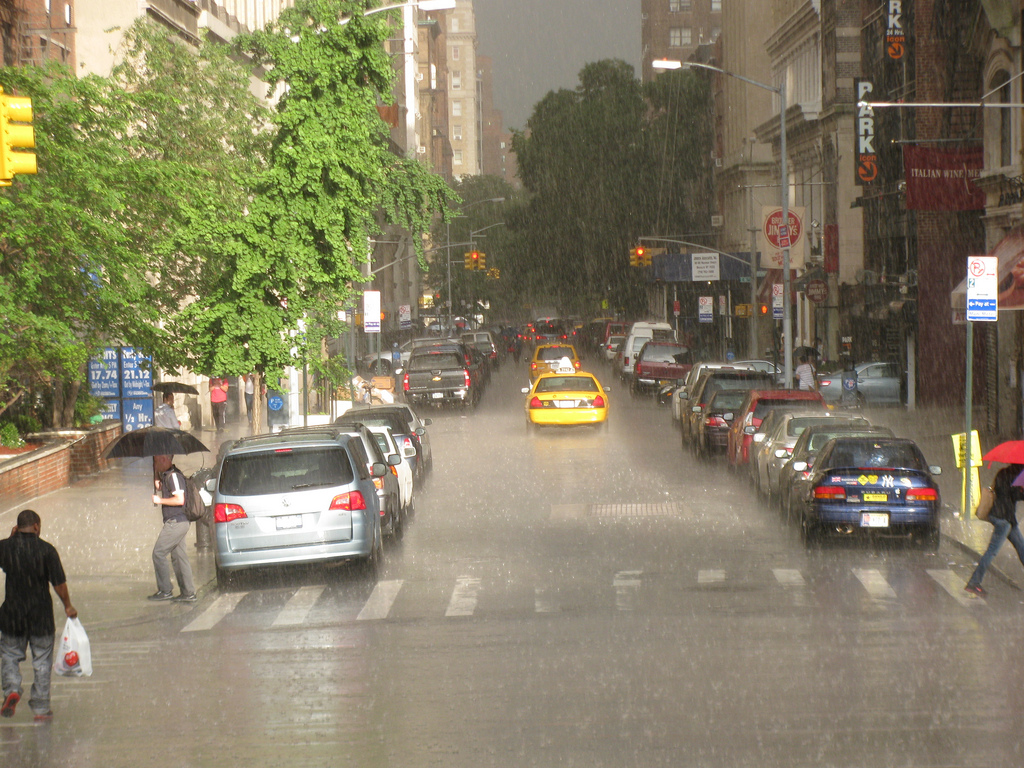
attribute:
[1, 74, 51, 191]
light — yellow, traffic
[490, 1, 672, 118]
sky — dark , grey, cloudy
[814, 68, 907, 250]
sign — vertical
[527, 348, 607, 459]
taxi — yellow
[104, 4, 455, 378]
leaves — green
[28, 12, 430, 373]
leaves — green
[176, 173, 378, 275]
leaves — green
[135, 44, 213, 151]
leaves — green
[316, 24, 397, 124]
leaves — green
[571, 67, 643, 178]
leaves — green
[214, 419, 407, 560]
car — parked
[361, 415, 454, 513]
car — parked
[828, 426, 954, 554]
car — parked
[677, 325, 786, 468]
car — parked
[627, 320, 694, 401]
car — parked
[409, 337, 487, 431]
car — parked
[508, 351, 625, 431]
car — driving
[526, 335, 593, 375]
car — driving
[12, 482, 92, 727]
man — walking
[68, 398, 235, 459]
umbrella — black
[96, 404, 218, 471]
umbrella — black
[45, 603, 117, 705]
bag — white 